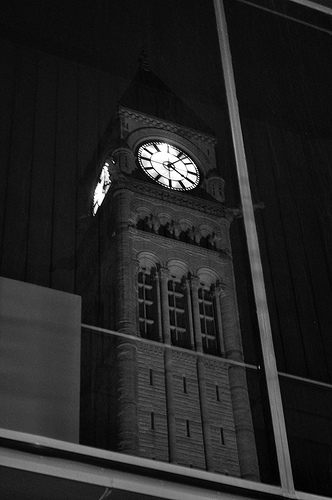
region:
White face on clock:
[136, 133, 214, 237]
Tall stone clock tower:
[117, 308, 266, 453]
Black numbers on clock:
[142, 139, 199, 237]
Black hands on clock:
[169, 153, 183, 184]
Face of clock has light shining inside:
[140, 127, 204, 216]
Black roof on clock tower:
[115, 65, 232, 148]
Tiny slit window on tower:
[142, 405, 164, 440]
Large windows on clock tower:
[129, 259, 250, 366]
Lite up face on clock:
[78, 151, 137, 228]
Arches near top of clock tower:
[130, 198, 238, 249]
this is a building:
[77, 56, 244, 441]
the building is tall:
[104, 37, 236, 442]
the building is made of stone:
[146, 389, 199, 407]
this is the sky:
[280, 36, 326, 103]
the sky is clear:
[51, 18, 113, 47]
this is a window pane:
[253, 387, 282, 438]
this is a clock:
[137, 108, 209, 202]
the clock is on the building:
[126, 127, 218, 236]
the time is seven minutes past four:
[168, 151, 193, 178]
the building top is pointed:
[112, 44, 191, 124]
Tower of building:
[60, 89, 274, 498]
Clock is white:
[128, 132, 206, 196]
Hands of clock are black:
[166, 148, 192, 178]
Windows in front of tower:
[131, 244, 233, 361]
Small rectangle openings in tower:
[143, 366, 236, 450]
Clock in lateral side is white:
[81, 153, 118, 223]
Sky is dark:
[8, 15, 326, 120]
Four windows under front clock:
[131, 201, 222, 256]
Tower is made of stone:
[80, 88, 271, 498]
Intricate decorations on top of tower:
[110, 104, 220, 145]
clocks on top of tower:
[77, 89, 232, 233]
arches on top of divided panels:
[129, 239, 222, 369]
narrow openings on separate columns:
[126, 342, 243, 458]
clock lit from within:
[133, 130, 198, 199]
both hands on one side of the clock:
[124, 117, 202, 200]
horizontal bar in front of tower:
[74, 310, 320, 383]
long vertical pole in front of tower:
[211, 19, 295, 486]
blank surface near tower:
[6, 267, 131, 455]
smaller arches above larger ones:
[127, 198, 227, 313]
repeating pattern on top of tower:
[119, 107, 222, 147]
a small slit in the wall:
[146, 406, 154, 429]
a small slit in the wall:
[182, 415, 191, 438]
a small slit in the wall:
[215, 426, 228, 446]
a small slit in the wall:
[145, 364, 156, 389]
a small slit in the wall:
[179, 372, 189, 395]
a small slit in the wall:
[212, 379, 224, 405]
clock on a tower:
[136, 139, 200, 191]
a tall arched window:
[134, 249, 163, 342]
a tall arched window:
[164, 257, 192, 349]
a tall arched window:
[194, 263, 227, 358]